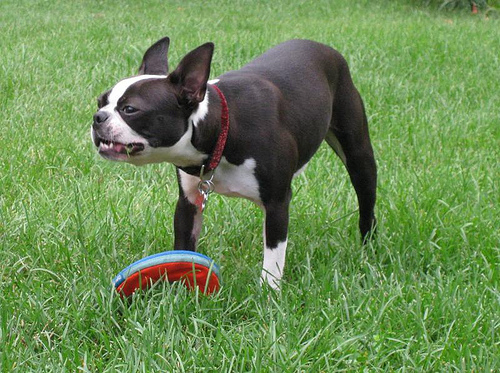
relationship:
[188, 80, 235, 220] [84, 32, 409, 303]
collar on dog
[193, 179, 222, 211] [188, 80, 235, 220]
tag on collar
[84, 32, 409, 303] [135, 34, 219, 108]
dog has ears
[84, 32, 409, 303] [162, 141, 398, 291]
dog has legs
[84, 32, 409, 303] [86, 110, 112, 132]
dog has nose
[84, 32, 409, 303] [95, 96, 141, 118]
dog has eyes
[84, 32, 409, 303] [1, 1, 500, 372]
dog in grass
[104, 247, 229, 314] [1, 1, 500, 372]
frisbee in grass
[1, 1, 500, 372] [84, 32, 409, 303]
grass near dog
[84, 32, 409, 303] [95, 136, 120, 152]
dog has teeth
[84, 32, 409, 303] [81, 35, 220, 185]
dog has head